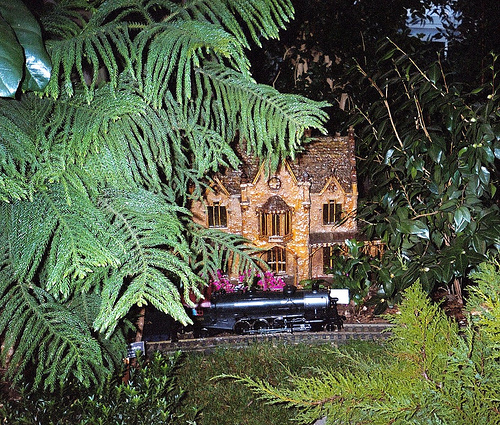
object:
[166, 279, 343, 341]
train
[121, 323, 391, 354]
tracks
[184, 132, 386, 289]
house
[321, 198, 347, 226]
window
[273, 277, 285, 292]
flower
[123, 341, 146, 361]
sign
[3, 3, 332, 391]
tree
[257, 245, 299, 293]
archway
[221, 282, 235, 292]
flower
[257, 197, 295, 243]
window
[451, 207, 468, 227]
leaf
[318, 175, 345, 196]
gable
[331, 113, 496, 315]
plant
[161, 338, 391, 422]
grass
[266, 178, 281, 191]
clock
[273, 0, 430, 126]
tree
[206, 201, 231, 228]
window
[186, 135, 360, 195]
roof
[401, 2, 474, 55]
sky